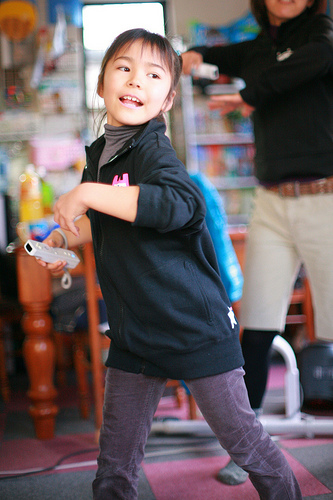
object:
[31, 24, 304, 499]
smiling woman